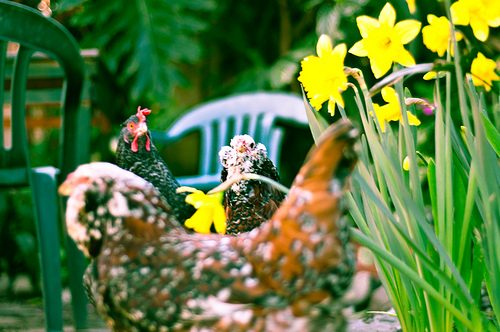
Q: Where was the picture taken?
A: Yard.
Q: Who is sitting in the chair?
A: Nobody.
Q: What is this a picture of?
A: Flowers.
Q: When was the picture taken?
A: Morning.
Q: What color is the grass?
A: Green.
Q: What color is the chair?
A: White.